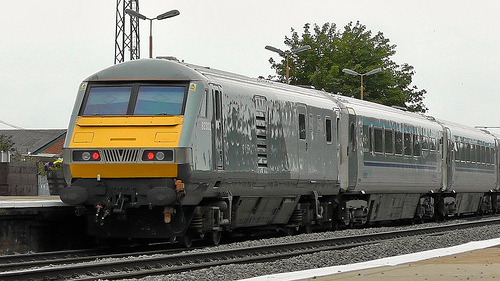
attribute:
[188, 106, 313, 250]
train — grey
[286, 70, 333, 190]
train — grey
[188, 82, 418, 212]
train — grey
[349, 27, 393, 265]
train — grey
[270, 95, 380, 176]
train — grey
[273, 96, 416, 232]
train — grey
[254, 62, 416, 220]
train — grey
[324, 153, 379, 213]
train — grey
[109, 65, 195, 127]
window — small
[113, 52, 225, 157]
window — small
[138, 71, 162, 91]
window — small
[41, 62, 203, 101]
window — small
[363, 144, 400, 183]
window — small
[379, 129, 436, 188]
window — small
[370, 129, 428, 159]
window — small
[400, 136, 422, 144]
window — small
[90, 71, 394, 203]
train — grey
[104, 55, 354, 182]
train — grey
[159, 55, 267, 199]
train — grey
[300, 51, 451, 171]
train — grey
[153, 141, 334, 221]
train — grey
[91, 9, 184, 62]
pole — distant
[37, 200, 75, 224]
dock — black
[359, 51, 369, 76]
tree — green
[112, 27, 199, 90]
tower — grey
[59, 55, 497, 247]
train — gray, Train car , Platform, silver  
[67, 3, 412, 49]
sky — foggy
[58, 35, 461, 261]
train — silver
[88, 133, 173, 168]
signals — red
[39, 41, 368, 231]
train — yellow and gray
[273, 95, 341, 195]
door — closed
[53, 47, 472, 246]
train — silver 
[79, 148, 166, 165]
lights — Line 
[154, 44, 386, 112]
top — Gray roof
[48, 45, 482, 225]
train — yellow front 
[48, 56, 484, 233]
train — silver  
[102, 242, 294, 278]
tracks — yellow 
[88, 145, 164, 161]
light — red 